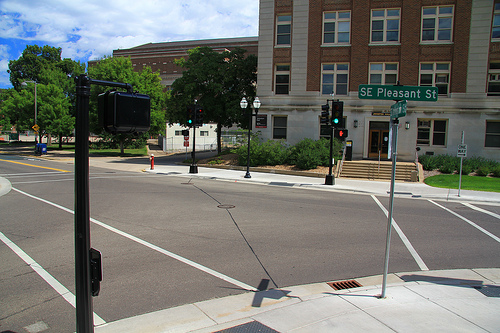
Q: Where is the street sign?
A: On the sidewalk.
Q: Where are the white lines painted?
A: On the road.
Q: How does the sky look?
A: Blue with some clouds.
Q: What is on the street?
A: White lines.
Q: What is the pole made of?
A: Metal.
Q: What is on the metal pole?
A: Sign.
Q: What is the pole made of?
A: Metal.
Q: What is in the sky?
A: Clouds.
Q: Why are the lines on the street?
A: Crosswalk.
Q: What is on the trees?
A: Leaves.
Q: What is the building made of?
A: Brick.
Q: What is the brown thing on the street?
A: Storm Drain.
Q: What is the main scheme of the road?
A: An intersection.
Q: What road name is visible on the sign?
A: SE Pleasant St.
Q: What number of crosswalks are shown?
A: 3.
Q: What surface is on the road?
A: Asphalt.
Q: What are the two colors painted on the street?
A: White and yellow.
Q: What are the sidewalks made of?
A: Concrete.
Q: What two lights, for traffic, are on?
A: Green.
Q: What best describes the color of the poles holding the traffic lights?
A: Black.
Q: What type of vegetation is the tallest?
A: The Trees.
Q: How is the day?
A: Sunny.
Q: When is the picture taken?
A: Daytime.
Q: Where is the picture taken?
A: On a sidewalk near a street corner.